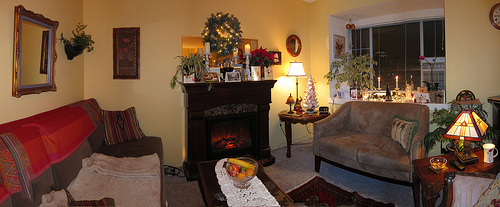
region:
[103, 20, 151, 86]
Picture on the wall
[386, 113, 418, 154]
Pillow on the sofa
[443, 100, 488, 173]
Lamp with glass shade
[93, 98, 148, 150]
Pillow on the sofa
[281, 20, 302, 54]
Mirror on the wall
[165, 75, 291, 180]
Fireplace on the wall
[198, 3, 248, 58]
Reef over the fireplace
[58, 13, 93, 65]
Flower pot on the wall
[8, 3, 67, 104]
Mirror over the sofa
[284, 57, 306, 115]
Lamp on the table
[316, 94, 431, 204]
a two person couch in a living room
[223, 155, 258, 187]
a bowl f fruit on a coffee table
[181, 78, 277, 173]
a fireplace in a living room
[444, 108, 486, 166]
a lamp on an end table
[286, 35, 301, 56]
a wooden frame oval mirror on the wall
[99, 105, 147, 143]
a colorful cushion on a sofa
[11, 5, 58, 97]
a golden frame mirror on a wall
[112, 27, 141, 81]
a framed painting on a wall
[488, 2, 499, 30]
edge of a clock on a wall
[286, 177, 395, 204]
colorful rug on a carpet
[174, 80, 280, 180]
Fire place in the living room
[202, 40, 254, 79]
Candles on the fire place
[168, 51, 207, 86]
Pot plant on the fire place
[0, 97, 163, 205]
Couch in the living room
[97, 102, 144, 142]
Pillow on the couch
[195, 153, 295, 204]
Coffee table in front of the couch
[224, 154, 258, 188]
Fruits on the coffee table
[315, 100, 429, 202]
Love seat in the living room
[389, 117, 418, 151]
Pillow on the love seat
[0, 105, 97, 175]
the blanket is red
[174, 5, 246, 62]
the reef has lights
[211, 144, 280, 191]
the bowl has fruit in it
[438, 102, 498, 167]
the lamp is turned on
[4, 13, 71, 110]
the mirror is on the wall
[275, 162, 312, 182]
the floor is of carpet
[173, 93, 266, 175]
the fireplace is on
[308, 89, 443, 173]
the sofa is brown hued.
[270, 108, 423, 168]
the sofa is sued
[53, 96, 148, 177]
the pillow is multicolored.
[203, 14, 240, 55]
wreathe above the fireplace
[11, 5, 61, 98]
framed mirror on the wall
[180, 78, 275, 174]
fire is burning in the fireplace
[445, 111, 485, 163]
the lamp is on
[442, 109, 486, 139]
the shade is stained glass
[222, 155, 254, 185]
a glass bowl full of fruit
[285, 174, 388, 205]
small area rug on the ground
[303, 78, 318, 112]
white decorative Christmas tree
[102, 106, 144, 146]
striped throw pillow on the couch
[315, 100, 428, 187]
beige love seat